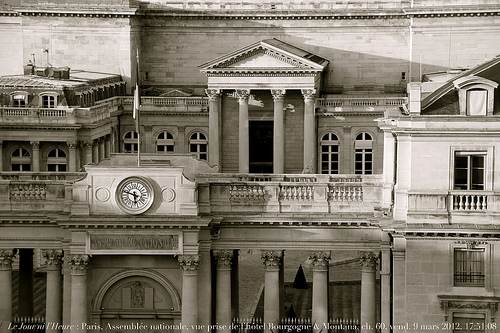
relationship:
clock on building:
[114, 178, 155, 215] [1, 1, 499, 331]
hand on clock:
[124, 190, 139, 203] [114, 178, 155, 215]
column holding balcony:
[214, 250, 231, 332] [1, 173, 377, 219]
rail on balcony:
[199, 182, 380, 217] [1, 173, 377, 219]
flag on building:
[132, 47, 144, 168] [1, 1, 499, 331]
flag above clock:
[132, 47, 144, 168] [114, 178, 155, 215]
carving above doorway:
[91, 236, 179, 250] [95, 270, 180, 332]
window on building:
[12, 93, 28, 111] [1, 1, 499, 331]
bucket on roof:
[25, 64, 36, 75] [1, 71, 120, 90]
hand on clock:
[120, 189, 142, 199] [114, 178, 155, 215]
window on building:
[40, 95, 55, 109] [1, 1, 499, 331]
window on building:
[456, 154, 468, 210] [1, 1, 499, 331]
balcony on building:
[1, 173, 377, 219] [1, 1, 499, 331]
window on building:
[465, 90, 488, 115] [1, 1, 499, 331]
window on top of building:
[465, 90, 488, 115] [1, 1, 499, 331]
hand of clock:
[124, 190, 139, 203] [114, 178, 155, 215]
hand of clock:
[120, 189, 142, 199] [114, 178, 155, 215]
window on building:
[319, 133, 341, 174] [1, 1, 499, 331]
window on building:
[354, 133, 372, 176] [1, 1, 499, 331]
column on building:
[231, 90, 251, 174] [1, 1, 499, 331]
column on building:
[260, 251, 284, 332] [1, 1, 499, 331]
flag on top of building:
[132, 47, 144, 168] [1, 1, 499, 331]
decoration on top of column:
[261, 249, 283, 271] [260, 251, 284, 332]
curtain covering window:
[468, 92, 488, 117] [465, 90, 488, 115]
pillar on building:
[231, 90, 251, 174] [0, 0, 499, 333]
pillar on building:
[308, 250, 334, 332] [0, 0, 499, 333]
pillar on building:
[270, 91, 286, 173] [0, 0, 499, 333]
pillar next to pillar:
[231, 90, 251, 174] [270, 91, 286, 173]